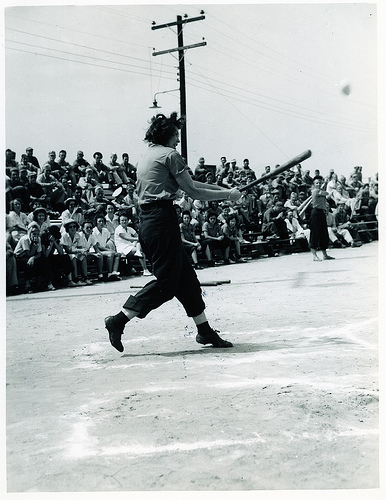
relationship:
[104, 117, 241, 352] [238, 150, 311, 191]
woman holding bat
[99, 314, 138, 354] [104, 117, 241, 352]
foot on woman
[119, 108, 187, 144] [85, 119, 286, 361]
head of a woman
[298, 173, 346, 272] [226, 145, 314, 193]
woman holding bat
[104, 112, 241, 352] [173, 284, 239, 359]
woman has foot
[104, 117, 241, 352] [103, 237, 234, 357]
woman has legs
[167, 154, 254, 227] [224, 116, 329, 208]
hand holding bat